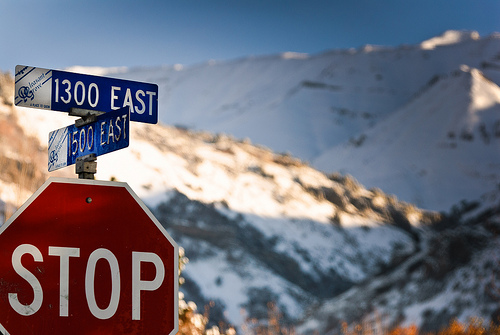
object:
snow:
[0, 30, 499, 335]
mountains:
[0, 30, 499, 335]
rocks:
[347, 195, 376, 213]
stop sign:
[0, 177, 180, 335]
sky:
[1, 1, 500, 73]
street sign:
[47, 104, 129, 172]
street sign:
[14, 64, 159, 125]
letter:
[7, 243, 44, 317]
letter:
[48, 245, 82, 318]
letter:
[84, 246, 121, 320]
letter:
[131, 251, 167, 323]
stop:
[7, 242, 168, 321]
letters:
[146, 89, 158, 116]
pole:
[76, 110, 97, 179]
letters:
[120, 113, 129, 139]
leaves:
[178, 319, 207, 335]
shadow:
[143, 188, 499, 335]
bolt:
[85, 197, 93, 204]